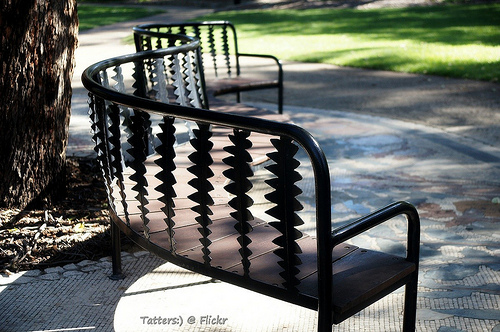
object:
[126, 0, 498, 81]
grass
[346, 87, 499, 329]
ground.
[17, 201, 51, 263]
twigs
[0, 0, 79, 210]
tree